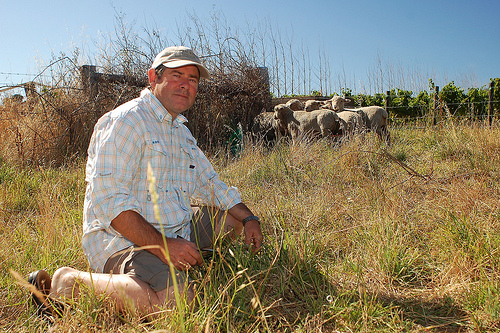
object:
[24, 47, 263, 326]
man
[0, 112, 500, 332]
field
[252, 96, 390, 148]
sheep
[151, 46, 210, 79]
hat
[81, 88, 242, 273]
shirt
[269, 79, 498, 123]
plants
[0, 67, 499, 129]
fence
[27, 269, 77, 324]
shoe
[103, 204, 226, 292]
shorts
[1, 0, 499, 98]
sky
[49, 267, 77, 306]
foot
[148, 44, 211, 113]
head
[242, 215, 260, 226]
wrist watch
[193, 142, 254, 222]
arm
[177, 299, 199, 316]
knees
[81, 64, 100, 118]
post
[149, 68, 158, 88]
ear